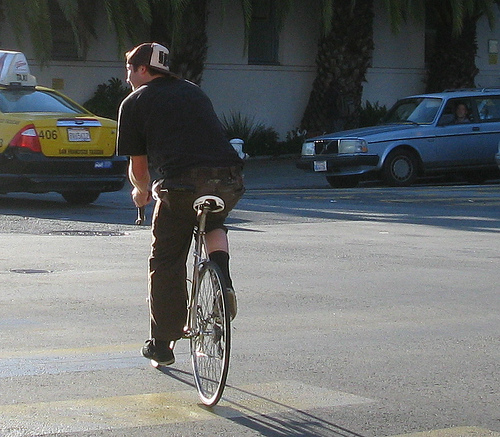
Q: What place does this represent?
A: It represents the pavement.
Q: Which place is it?
A: It is a pavement.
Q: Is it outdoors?
A: Yes, it is outdoors.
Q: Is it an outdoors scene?
A: Yes, it is outdoors.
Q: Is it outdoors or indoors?
A: It is outdoors.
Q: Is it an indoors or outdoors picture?
A: It is outdoors.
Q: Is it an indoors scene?
A: No, it is outdoors.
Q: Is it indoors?
A: No, it is outdoors.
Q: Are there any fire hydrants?
A: Yes, there is a fire hydrant.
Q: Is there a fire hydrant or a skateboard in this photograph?
A: Yes, there is a fire hydrant.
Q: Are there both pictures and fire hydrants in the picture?
A: No, there is a fire hydrant but no pictures.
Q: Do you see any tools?
A: No, there are no tools.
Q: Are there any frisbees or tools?
A: No, there are no tools or frisbees.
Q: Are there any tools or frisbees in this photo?
A: No, there are no tools or frisbees.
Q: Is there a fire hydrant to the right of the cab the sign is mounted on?
A: Yes, there is a fire hydrant to the right of the taxi cab.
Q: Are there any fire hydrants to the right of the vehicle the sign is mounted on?
A: Yes, there is a fire hydrant to the right of the taxi cab.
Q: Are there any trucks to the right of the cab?
A: No, there is a fire hydrant to the right of the cab.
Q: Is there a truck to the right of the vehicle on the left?
A: No, there is a fire hydrant to the right of the cab.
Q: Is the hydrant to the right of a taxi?
A: Yes, the hydrant is to the right of a taxi.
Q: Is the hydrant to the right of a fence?
A: No, the hydrant is to the right of a taxi.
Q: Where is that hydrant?
A: The hydrant is on the sidewalk.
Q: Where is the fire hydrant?
A: The hydrant is on the sidewalk.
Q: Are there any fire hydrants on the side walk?
A: Yes, there is a fire hydrant on the side walk.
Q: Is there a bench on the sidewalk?
A: No, there is a fire hydrant on the sidewalk.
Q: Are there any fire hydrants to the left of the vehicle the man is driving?
A: Yes, there is a fire hydrant to the left of the car.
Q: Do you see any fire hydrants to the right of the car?
A: No, the fire hydrant is to the left of the car.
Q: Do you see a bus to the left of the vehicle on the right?
A: No, there is a fire hydrant to the left of the car.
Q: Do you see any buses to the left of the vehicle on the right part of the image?
A: No, there is a fire hydrant to the left of the car.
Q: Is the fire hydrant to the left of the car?
A: Yes, the fire hydrant is to the left of the car.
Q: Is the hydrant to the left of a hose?
A: No, the hydrant is to the left of the car.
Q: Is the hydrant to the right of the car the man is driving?
A: No, the hydrant is to the left of the car.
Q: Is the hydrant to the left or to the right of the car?
A: The hydrant is to the left of the car.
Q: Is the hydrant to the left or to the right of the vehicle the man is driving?
A: The hydrant is to the left of the car.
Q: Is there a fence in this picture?
A: No, there are no fences.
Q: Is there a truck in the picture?
A: No, there are no trucks.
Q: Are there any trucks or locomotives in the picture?
A: No, there are no trucks or locomotives.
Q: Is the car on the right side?
A: Yes, the car is on the right of the image.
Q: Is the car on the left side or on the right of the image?
A: The car is on the right of the image.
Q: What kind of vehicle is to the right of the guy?
A: The vehicle is a car.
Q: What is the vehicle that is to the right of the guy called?
A: The vehicle is a car.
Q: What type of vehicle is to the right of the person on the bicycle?
A: The vehicle is a car.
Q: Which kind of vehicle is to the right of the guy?
A: The vehicle is a car.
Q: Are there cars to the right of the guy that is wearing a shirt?
A: Yes, there is a car to the right of the guy.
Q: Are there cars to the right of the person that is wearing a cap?
A: Yes, there is a car to the right of the guy.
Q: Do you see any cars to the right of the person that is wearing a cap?
A: Yes, there is a car to the right of the guy.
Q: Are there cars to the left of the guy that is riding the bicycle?
A: No, the car is to the right of the guy.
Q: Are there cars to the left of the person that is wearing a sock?
A: No, the car is to the right of the guy.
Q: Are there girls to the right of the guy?
A: No, there is a car to the right of the guy.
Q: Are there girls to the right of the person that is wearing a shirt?
A: No, there is a car to the right of the guy.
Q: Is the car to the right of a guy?
A: Yes, the car is to the right of a guy.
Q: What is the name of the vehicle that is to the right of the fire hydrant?
A: The vehicle is a car.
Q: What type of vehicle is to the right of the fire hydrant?
A: The vehicle is a car.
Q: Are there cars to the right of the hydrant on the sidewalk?
A: Yes, there is a car to the right of the fire hydrant.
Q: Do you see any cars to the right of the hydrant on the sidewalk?
A: Yes, there is a car to the right of the fire hydrant.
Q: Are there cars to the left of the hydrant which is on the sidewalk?
A: No, the car is to the right of the fire hydrant.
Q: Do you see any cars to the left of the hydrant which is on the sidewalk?
A: No, the car is to the right of the fire hydrant.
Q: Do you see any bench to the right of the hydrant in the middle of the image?
A: No, there is a car to the right of the hydrant.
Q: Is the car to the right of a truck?
A: No, the car is to the right of a fire hydrant.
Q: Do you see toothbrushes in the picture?
A: No, there are no toothbrushes.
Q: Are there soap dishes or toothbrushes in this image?
A: No, there are no toothbrushes or soap dishes.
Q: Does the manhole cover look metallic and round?
A: Yes, the manhole cover is metallic and round.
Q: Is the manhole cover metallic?
A: Yes, the manhole cover is metallic.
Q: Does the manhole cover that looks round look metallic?
A: Yes, the manhole cover is metallic.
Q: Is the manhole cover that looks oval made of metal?
A: Yes, the manhole cover is made of metal.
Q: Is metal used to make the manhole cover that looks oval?
A: Yes, the manhole cover is made of metal.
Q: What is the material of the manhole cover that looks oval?
A: The manhole cover is made of metal.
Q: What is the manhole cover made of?
A: The manhole cover is made of metal.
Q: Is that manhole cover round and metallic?
A: Yes, the manhole cover is round and metallic.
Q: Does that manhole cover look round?
A: Yes, the manhole cover is round.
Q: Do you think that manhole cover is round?
A: Yes, the manhole cover is round.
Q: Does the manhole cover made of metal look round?
A: Yes, the manhole cover is round.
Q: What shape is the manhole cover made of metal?
A: The manhole cover is round.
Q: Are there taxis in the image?
A: Yes, there is a taxi.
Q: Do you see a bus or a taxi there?
A: Yes, there is a taxi.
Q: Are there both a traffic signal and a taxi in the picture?
A: No, there is a taxi but no traffic lights.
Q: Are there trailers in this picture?
A: No, there are no trailers.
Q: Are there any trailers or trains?
A: No, there are no trailers or trains.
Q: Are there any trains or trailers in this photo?
A: No, there are no trailers or trains.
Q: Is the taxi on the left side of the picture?
A: Yes, the taxi is on the left of the image.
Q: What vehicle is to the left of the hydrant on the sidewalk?
A: The vehicle is a taxi.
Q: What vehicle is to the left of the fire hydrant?
A: The vehicle is a taxi.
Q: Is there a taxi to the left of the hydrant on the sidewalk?
A: Yes, there is a taxi to the left of the hydrant.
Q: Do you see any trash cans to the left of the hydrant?
A: No, there is a taxi to the left of the hydrant.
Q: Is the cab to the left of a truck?
A: No, the cab is to the left of the hydrant.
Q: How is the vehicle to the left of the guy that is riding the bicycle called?
A: The vehicle is a taxi.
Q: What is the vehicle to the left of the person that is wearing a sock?
A: The vehicle is a taxi.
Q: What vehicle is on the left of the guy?
A: The vehicle is a taxi.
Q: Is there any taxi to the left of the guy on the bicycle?
A: Yes, there is a taxi to the left of the guy.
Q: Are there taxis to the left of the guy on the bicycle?
A: Yes, there is a taxi to the left of the guy.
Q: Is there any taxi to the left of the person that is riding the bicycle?
A: Yes, there is a taxi to the left of the guy.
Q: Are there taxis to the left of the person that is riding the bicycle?
A: Yes, there is a taxi to the left of the guy.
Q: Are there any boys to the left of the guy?
A: No, there is a taxi to the left of the guy.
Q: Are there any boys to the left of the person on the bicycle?
A: No, there is a taxi to the left of the guy.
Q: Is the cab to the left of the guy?
A: Yes, the cab is to the left of the guy.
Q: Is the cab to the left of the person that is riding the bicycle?
A: Yes, the cab is to the left of the guy.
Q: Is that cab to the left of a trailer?
A: No, the cab is to the left of the guy.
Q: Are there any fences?
A: No, there are no fences.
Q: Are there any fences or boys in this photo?
A: No, there are no fences or boys.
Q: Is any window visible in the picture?
A: Yes, there is a window.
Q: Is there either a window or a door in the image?
A: Yes, there is a window.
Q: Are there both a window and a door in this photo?
A: No, there is a window but no doors.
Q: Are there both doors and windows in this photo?
A: No, there is a window but no doors.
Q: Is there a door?
A: No, there are no doors.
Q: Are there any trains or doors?
A: No, there are no doors or trains.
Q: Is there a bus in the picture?
A: No, there are no buses.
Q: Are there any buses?
A: No, there are no buses.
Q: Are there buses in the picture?
A: No, there are no buses.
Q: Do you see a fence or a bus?
A: No, there are no buses or fences.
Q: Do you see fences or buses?
A: No, there are no buses or fences.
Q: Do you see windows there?
A: Yes, there is a window.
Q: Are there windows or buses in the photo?
A: Yes, there is a window.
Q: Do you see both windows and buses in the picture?
A: No, there is a window but no buses.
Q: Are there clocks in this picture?
A: No, there are no clocks.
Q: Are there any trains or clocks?
A: No, there are no clocks or trains.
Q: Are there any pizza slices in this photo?
A: No, there are no pizza slices.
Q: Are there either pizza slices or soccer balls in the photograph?
A: No, there are no pizza slices or soccer balls.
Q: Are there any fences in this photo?
A: No, there are no fences.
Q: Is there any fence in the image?
A: No, there are no fences.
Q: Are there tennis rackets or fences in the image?
A: No, there are no fences or tennis rackets.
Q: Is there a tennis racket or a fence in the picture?
A: No, there are no fences or rackets.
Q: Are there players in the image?
A: No, there are no players.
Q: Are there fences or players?
A: No, there are no players or fences.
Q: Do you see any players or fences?
A: No, there are no players or fences.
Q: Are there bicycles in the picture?
A: Yes, there is a bicycle.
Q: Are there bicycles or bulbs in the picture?
A: Yes, there is a bicycle.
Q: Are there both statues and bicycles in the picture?
A: No, there is a bicycle but no statues.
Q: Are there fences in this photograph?
A: No, there are no fences.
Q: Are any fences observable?
A: No, there are no fences.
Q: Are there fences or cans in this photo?
A: No, there are no fences or cans.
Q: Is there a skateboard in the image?
A: No, there are no skateboards.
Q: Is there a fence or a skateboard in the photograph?
A: No, there are no skateboards or fences.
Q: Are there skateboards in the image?
A: No, there are no skateboards.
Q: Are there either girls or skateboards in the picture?
A: No, there are no skateboards or girls.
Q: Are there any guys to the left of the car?
A: Yes, there is a guy to the left of the car.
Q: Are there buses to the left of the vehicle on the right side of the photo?
A: No, there is a guy to the left of the car.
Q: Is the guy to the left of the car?
A: Yes, the guy is to the left of the car.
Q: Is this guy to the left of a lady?
A: No, the guy is to the left of the car.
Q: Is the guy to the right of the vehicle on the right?
A: No, the guy is to the left of the car.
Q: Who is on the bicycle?
A: The guy is on the bicycle.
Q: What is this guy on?
A: The guy is on the bicycle.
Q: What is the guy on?
A: The guy is on the bicycle.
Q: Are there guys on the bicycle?
A: Yes, there is a guy on the bicycle.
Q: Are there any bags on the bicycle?
A: No, there is a guy on the bicycle.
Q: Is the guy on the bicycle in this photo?
A: Yes, the guy is on the bicycle.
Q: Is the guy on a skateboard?
A: No, the guy is on the bicycle.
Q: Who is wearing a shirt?
A: The guy is wearing a shirt.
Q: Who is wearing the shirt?
A: The guy is wearing a shirt.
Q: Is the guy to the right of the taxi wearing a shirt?
A: Yes, the guy is wearing a shirt.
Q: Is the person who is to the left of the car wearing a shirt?
A: Yes, the guy is wearing a shirt.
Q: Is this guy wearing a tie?
A: No, the guy is wearing a shirt.